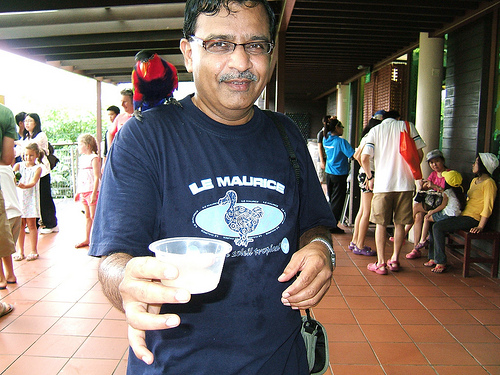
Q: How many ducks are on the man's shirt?
A: One.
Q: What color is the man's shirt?
A: Blue.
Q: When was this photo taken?
A: Daytime.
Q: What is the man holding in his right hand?
A: Plastic cup.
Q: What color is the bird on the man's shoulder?
A: Red.